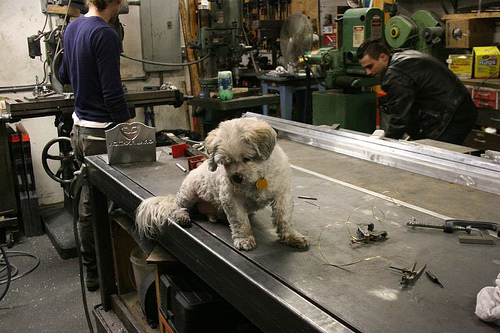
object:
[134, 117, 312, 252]
dog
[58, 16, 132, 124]
shirt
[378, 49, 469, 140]
jacket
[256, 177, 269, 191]
tag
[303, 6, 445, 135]
equipment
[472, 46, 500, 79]
box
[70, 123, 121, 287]
pants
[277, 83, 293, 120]
leg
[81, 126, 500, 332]
table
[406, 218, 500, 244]
vice grip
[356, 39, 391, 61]
hair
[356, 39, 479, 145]
man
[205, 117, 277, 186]
head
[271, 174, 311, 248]
leg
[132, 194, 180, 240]
tail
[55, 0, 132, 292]
person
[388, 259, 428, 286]
tool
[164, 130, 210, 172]
tool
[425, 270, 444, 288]
tool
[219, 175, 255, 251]
leg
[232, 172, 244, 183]
nose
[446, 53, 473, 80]
box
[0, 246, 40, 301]
cord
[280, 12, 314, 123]
house fan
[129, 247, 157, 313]
bucket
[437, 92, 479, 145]
pants